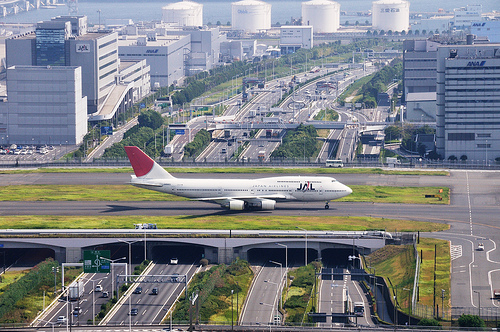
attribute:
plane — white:
[123, 141, 354, 211]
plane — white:
[119, 136, 356, 219]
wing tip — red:
[125, 144, 162, 179]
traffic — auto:
[79, 249, 181, 274]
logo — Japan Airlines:
[293, 178, 319, 196]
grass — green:
[5, 216, 435, 230]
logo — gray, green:
[462, 56, 493, 77]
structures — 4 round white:
[137, 0, 423, 47]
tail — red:
[117, 139, 171, 194]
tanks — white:
[163, 0, 418, 34]